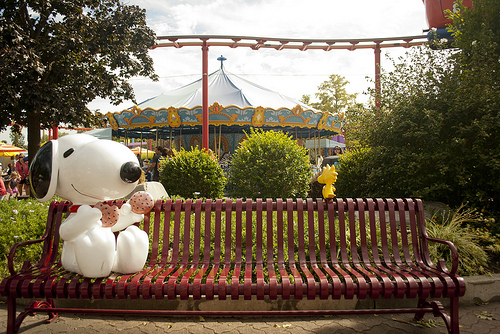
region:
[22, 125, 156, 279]
snoopy toy on bench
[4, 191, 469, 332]
a red metal bench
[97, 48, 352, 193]
carousel behind the bench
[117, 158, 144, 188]
the nose on snoopy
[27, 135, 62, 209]
snoopy's right ear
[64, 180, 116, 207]
smile on snoopy's face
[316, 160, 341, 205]
woodstock on the bench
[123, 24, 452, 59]
red metal roller coaster track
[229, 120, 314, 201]
big round bush behind the bench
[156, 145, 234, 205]
small round bush behind the bench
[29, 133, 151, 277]
large Snoopy doll on a bench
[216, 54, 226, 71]
cross on top of a carousel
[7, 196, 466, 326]
metal bench in a park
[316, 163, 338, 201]
a yellow creature in the park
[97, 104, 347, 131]
the rim of a carousel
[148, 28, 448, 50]
OVERHEAD TRAIN TRACK IN THE PARK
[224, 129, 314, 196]
a bush that needs a trim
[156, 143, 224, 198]
small bush beside a large bush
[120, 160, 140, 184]
round black nose of snoopy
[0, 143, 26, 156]
red and yellow awning in the distance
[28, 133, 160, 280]
Snoopy sitting on a bench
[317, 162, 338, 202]
Woodstock doll perched on top of the bench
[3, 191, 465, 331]
Red park bench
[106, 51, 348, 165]
Carousel in the background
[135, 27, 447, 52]
Roller coaster track in the air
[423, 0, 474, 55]
Red roller coaster car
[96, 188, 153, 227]
Chocolate chip cookies in Snoopy's hands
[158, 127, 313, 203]
Bushes in front of the carousel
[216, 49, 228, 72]
Cross on top of the carousel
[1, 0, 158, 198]
Tree to the left of the carousel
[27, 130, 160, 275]
Snoopy with two cookies in his hands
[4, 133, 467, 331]
Snoopy sitting on a red metal bench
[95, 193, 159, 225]
Two pink and black sprinkled cookies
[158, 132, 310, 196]
Two green bushes in front of carousel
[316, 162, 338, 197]
Woodstock figure near green bush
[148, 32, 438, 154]
Red rollercoaster track in front of carousel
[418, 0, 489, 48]
Red rollercoaster car on tracks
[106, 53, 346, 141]
Blue and yellow tent of carousel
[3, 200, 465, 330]
Red metal bench sitting on brick pathway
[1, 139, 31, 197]
Several people near red and yellow tent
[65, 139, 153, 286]
snoopy is white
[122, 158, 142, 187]
the nose is black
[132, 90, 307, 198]
merry go round behind bushes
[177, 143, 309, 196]
the bushes are green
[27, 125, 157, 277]
White dog sculpture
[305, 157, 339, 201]
Yellow bird sculpture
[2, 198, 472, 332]
Red metal bench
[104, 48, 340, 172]
Carousel with blue and yellow tent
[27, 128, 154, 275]
Statue of dog holding cookies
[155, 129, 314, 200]
Two large green shrubs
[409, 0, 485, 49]
Red and blue roller coaster car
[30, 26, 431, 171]
Orange roller coaster track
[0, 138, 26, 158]
Red white and yellow tent